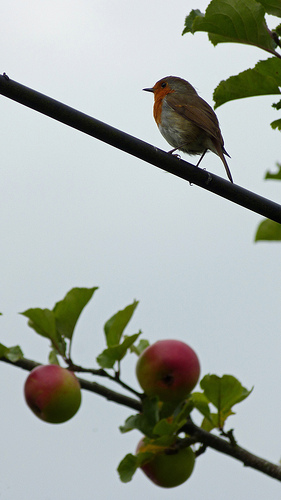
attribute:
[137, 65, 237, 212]
bird — small, grey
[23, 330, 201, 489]
apples — growing, fruit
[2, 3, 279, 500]
tree — green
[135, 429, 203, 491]
apples — green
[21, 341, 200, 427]
apples — red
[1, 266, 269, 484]
leaves — green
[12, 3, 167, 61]
sky — overcast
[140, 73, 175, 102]
bird's — orange chest, face, orange face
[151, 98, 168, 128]
bird's — orange chest, face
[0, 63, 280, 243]
rod — black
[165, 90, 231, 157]
long — feathers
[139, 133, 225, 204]
claw — curved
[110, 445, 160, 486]
small — leaf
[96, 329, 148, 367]
green — leaf